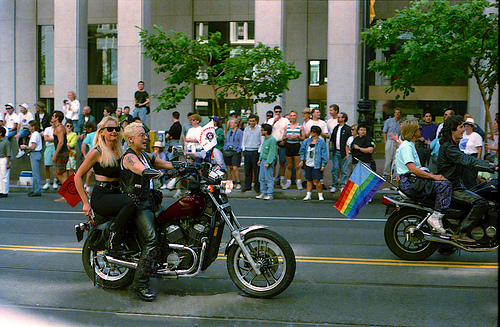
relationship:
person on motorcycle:
[119, 122, 206, 300] [75, 148, 296, 297]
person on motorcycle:
[74, 115, 136, 252] [75, 148, 296, 297]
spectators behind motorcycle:
[0, 81, 500, 202] [75, 148, 296, 297]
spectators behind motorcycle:
[0, 81, 500, 202] [383, 164, 499, 259]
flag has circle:
[59, 173, 89, 207] [67, 182, 81, 195]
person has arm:
[119, 122, 206, 300] [123, 153, 181, 176]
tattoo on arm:
[126, 156, 136, 167] [123, 153, 181, 176]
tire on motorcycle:
[81, 231, 137, 291] [75, 148, 296, 297]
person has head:
[119, 122, 206, 300] [126, 122, 148, 151]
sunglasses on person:
[101, 126, 122, 131] [74, 115, 136, 252]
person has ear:
[74, 115, 136, 252] [100, 129, 104, 136]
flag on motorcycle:
[332, 160, 386, 220] [383, 164, 499, 259]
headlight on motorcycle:
[218, 181, 234, 194] [75, 148, 296, 297]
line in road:
[2, 244, 500, 270] [1, 193, 500, 326]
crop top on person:
[93, 144, 121, 178] [74, 115, 136, 252]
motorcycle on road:
[75, 148, 296, 297] [1, 193, 500, 326]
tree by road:
[135, 25, 301, 129] [1, 193, 500, 326]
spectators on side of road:
[0, 81, 500, 202] [1, 193, 500, 326]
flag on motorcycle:
[59, 173, 89, 207] [75, 148, 296, 297]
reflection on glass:
[41, 26, 467, 140] [38, 26, 466, 139]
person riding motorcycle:
[119, 122, 206, 300] [75, 148, 296, 297]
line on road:
[2, 244, 500, 270] [1, 193, 500, 326]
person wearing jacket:
[297, 126, 330, 202] [299, 137, 328, 168]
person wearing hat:
[14, 105, 35, 159] [19, 103, 29, 111]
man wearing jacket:
[434, 114, 499, 245] [437, 141, 495, 192]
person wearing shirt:
[282, 109, 306, 191] [287, 122, 303, 144]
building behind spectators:
[1, 1, 500, 160] [0, 81, 500, 202]